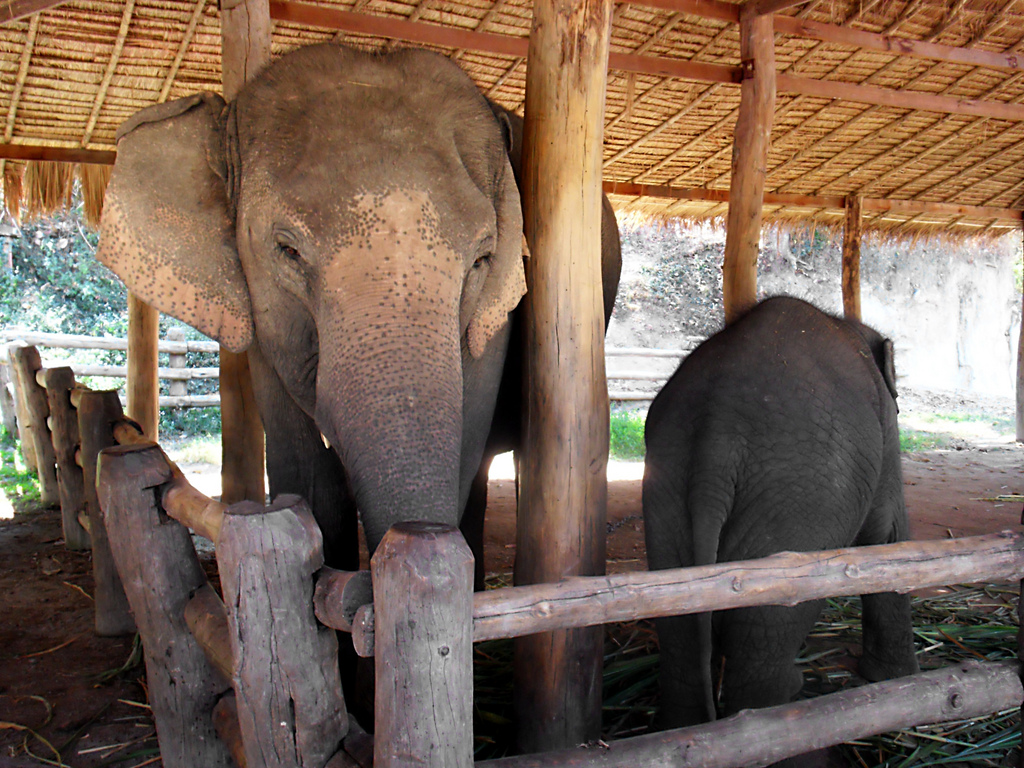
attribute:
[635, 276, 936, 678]
elephant — smaller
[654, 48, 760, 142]
roof — wooden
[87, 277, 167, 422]
beam — a support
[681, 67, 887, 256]
beam — wooden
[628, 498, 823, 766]
legs — back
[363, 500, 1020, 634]
rail — top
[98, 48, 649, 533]
elephant — large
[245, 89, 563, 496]
face — light colored speckled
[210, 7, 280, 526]
support beam — wooden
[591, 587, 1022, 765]
reeds — green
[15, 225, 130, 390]
vines — green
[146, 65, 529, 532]
elephant — large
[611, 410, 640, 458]
grass — green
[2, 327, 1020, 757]
fence — low, split-rail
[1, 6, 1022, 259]
roof — thatch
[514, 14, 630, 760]
support beam — wooden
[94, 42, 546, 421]
head — gray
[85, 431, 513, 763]
fence — wooden post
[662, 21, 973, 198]
roof — wooden slat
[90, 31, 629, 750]
elephant — tanish